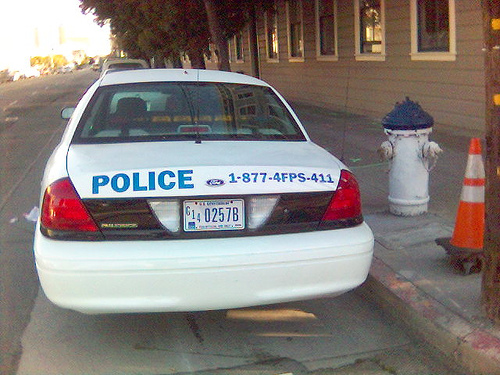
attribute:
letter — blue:
[91, 170, 110, 194]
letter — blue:
[130, 170, 145, 190]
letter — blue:
[149, 170, 156, 188]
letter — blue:
[173, 167, 193, 190]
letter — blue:
[108, 169, 132, 191]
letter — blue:
[130, 170, 150, 190]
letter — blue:
[156, 169, 175, 188]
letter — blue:
[146, 169, 156, 189]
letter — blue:
[126, 169, 148, 191]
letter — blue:
[145, 170, 155, 189]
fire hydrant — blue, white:
[376, 95, 446, 215]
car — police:
[28, 59, 386, 324]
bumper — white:
[24, 221, 384, 321]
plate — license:
[176, 191, 246, 237]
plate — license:
[178, 194, 251, 239]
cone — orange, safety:
[445, 133, 491, 250]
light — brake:
[324, 167, 366, 231]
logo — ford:
[201, 179, 226, 188]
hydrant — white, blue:
[374, 90, 445, 216]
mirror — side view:
[58, 104, 74, 121]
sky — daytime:
[12, 11, 103, 71]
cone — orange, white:
[434, 136, 480, 261]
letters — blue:
[88, 168, 196, 195]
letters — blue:
[281, 167, 304, 181]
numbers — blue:
[228, 169, 280, 186]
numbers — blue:
[309, 168, 337, 182]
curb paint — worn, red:
[373, 242, 460, 367]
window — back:
[73, 76, 308, 146]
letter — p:
[90, 168, 110, 197]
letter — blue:
[110, 170, 130, 197]